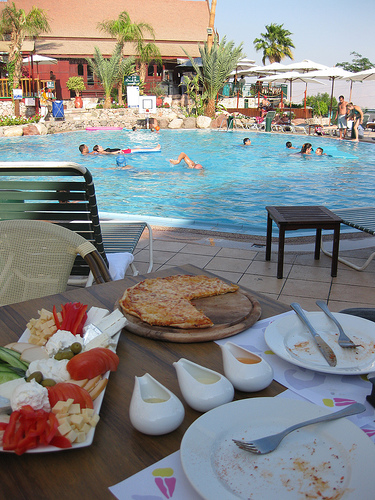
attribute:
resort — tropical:
[2, 0, 374, 122]